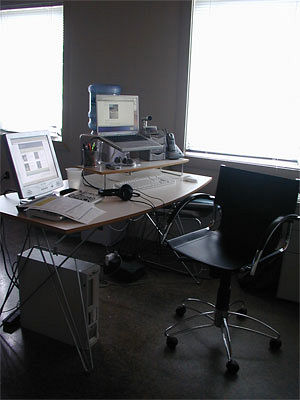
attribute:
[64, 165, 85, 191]
cup — clear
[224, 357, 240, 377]
wheel — black, plastic